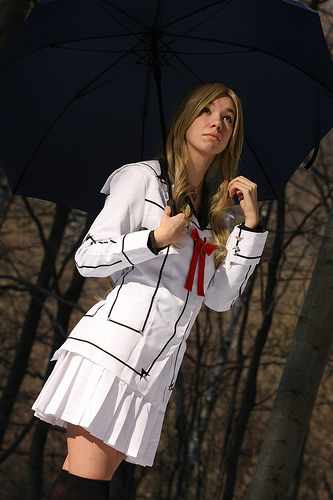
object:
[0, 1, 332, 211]
umbrella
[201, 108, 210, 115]
eyes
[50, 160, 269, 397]
jacket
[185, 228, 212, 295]
bow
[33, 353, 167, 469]
skirt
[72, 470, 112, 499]
stockings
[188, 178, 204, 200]
necklace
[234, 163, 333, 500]
tree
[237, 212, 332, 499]
trunk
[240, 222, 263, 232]
shirt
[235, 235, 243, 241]
button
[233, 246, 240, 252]
button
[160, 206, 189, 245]
hand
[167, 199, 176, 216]
handle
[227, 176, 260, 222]
hand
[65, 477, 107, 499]
knee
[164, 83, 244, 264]
hair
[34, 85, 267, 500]
woman